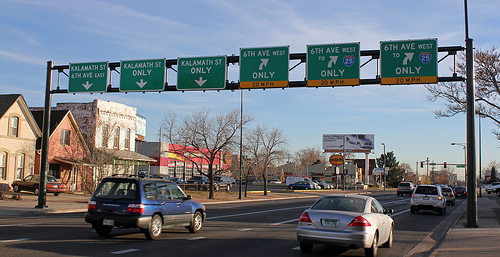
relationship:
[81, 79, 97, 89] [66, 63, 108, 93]
arrow on sign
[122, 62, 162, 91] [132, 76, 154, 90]
sign has arrow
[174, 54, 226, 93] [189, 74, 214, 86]
sign has arrow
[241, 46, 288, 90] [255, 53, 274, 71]
sign has arrow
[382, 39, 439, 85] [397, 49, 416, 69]
sign has arrow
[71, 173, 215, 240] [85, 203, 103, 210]
car has tail light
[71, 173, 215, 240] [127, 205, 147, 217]
car has tail light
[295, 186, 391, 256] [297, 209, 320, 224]
car has tail light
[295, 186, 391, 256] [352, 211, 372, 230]
car has tail light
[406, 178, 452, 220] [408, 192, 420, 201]
car has tail light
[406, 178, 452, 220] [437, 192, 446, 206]
car has tail light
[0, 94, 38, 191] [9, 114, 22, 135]
house has window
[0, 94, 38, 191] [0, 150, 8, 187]
house has window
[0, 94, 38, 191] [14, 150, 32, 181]
house has window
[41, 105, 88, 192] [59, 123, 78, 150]
house has window